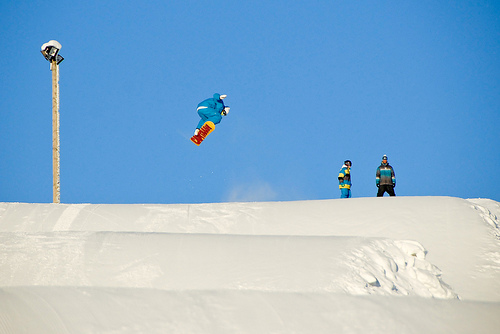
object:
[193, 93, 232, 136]
person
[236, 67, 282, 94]
air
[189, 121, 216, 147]
snowboard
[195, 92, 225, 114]
jacket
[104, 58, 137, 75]
sky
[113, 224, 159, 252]
ground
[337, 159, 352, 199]
man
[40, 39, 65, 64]
light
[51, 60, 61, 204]
pole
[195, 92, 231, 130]
outfit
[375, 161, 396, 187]
clothes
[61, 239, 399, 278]
snow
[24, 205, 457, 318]
hill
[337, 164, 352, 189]
coat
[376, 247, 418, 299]
track